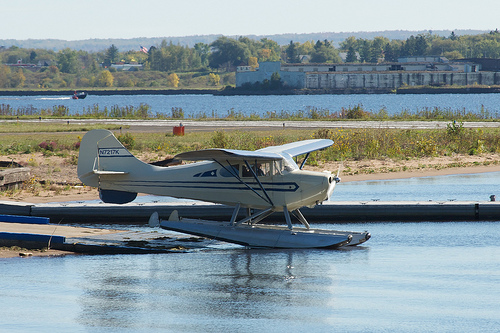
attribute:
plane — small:
[71, 125, 373, 253]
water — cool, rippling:
[0, 166, 500, 331]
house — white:
[230, 62, 499, 95]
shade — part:
[216, 240, 341, 310]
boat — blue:
[73, 93, 88, 100]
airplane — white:
[60, 125, 341, 212]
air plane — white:
[65, 119, 380, 259]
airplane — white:
[78, 116, 371, 253]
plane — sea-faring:
[52, 104, 416, 289]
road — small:
[244, 103, 371, 143]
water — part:
[243, 259, 478, 329]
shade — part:
[209, 269, 309, 311]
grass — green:
[3, 64, 497, 184]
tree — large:
[152, 43, 241, 85]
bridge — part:
[0, 198, 498, 223]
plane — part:
[38, 123, 363, 265]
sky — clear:
[0, 0, 498, 41]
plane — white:
[23, 103, 373, 290]